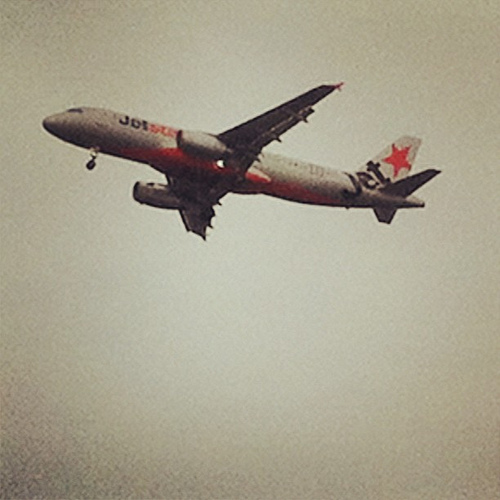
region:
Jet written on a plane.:
[338, 153, 409, 195]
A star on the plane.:
[392, 138, 423, 183]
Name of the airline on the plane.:
[112, 113, 189, 144]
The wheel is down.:
[85, 151, 119, 188]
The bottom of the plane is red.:
[123, 135, 251, 196]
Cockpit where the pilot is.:
[51, 110, 106, 124]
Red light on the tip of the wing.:
[309, 67, 372, 104]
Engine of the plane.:
[171, 132, 248, 161]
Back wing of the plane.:
[391, 123, 421, 180]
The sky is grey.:
[212, 267, 300, 289]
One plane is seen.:
[50, 92, 438, 235]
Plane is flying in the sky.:
[30, 82, 455, 249]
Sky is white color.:
[90, 307, 420, 444]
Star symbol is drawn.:
[375, 136, 420, 167]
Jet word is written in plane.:
[340, 150, 390, 210]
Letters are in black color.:
[345, 160, 385, 195]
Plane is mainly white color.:
[35, 95, 410, 210]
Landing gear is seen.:
[72, 151, 107, 176]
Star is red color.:
[383, 140, 416, 168]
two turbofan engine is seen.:
[131, 129, 230, 211]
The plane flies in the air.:
[28, 55, 463, 252]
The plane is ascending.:
[20, 46, 479, 253]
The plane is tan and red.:
[24, 66, 458, 258]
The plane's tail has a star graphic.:
[377, 142, 419, 180]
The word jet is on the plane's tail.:
[331, 155, 392, 205]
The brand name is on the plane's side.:
[108, 107, 192, 143]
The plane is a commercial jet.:
[20, 62, 470, 252]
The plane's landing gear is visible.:
[75, 143, 110, 172]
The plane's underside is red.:
[114, 142, 339, 211]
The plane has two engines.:
[103, 110, 268, 241]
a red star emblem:
[380, 142, 427, 184]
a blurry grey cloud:
[47, 267, 439, 454]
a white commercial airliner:
[29, 74, 485, 356]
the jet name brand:
[104, 104, 199, 146]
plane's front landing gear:
[81, 138, 108, 175]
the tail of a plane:
[358, 115, 442, 233]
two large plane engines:
[126, 119, 238, 228]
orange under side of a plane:
[118, 129, 334, 207]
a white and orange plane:
[24, 75, 464, 247]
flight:
[32, 17, 471, 327]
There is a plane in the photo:
[52, 65, 492, 320]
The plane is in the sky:
[42, 65, 492, 295]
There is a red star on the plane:
[313, 13, 460, 275]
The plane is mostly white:
[35, 68, 482, 318]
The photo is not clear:
[35, 54, 495, 365]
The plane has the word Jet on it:
[40, 46, 479, 291]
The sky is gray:
[50, 37, 497, 314]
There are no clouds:
[55, 57, 498, 391]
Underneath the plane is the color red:
[55, 73, 465, 313]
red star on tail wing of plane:
[375, 131, 427, 181]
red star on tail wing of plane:
[373, 135, 430, 183]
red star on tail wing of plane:
[367, 132, 427, 184]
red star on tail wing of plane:
[371, 133, 423, 183]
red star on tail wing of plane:
[375, 133, 422, 184]